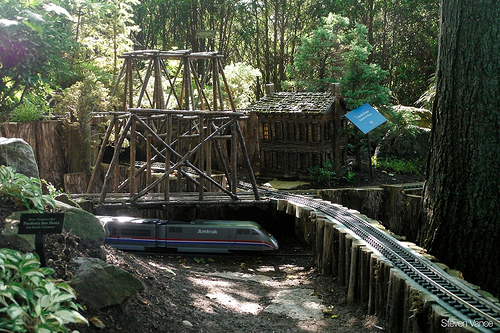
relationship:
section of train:
[157, 220, 277, 261] [3, 216, 279, 255]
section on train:
[87, 213, 161, 259] [96, 211, 283, 261]